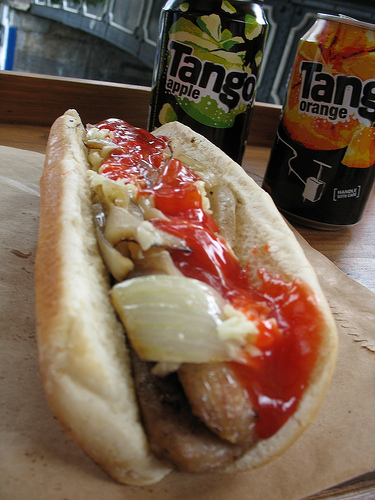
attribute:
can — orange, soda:
[268, 0, 355, 224]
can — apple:
[152, 2, 261, 161]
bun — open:
[35, 96, 341, 484]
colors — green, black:
[148, 29, 246, 133]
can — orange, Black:
[285, 7, 352, 227]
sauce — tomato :
[262, 291, 308, 357]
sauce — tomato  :
[273, 291, 305, 339]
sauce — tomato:
[275, 313, 311, 353]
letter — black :
[224, 73, 251, 106]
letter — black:
[297, 57, 321, 108]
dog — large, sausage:
[38, 109, 333, 476]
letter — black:
[162, 33, 196, 91]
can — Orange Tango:
[255, 7, 373, 229]